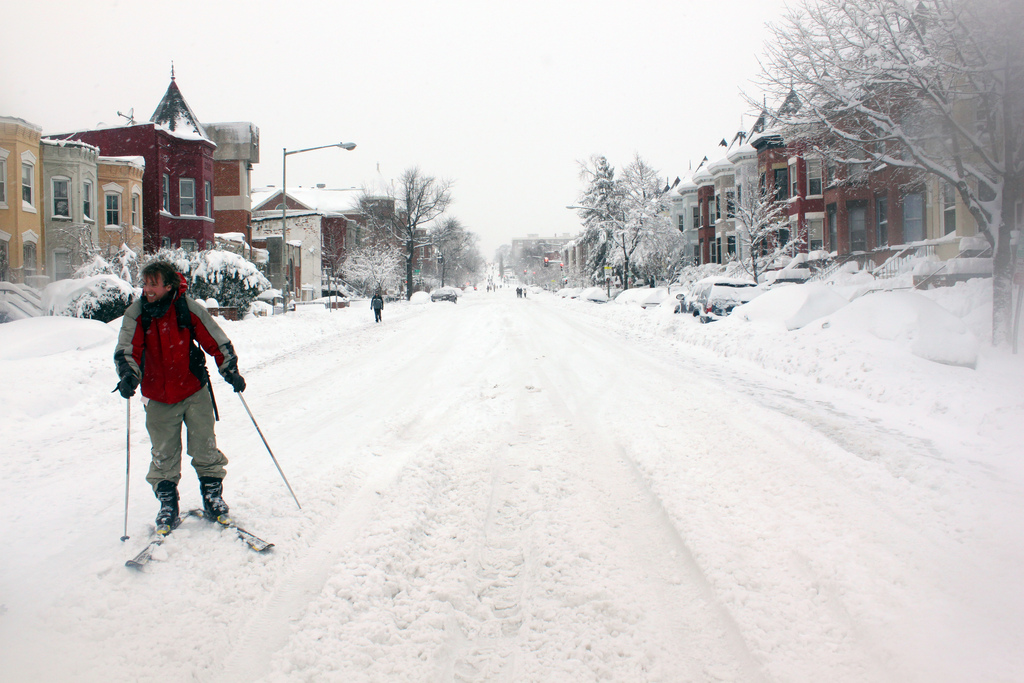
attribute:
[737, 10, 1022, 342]
tree — bare